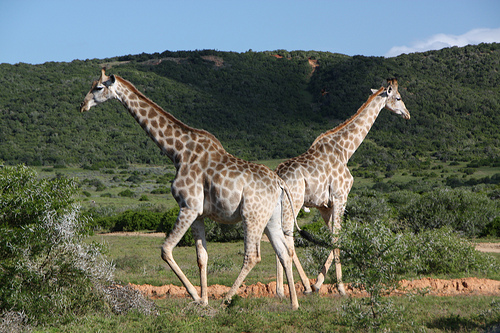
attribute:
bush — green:
[12, 159, 112, 328]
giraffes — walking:
[78, 64, 410, 311]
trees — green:
[431, 63, 476, 140]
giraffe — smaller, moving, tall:
[275, 78, 410, 299]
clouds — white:
[382, 22, 499, 57]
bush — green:
[334, 215, 474, 290]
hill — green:
[8, 45, 500, 208]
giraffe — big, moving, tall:
[75, 62, 302, 317]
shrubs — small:
[1, 164, 157, 331]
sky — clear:
[0, 1, 500, 64]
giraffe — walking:
[75, 67, 332, 313]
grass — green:
[0, 159, 497, 331]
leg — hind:
[217, 188, 274, 308]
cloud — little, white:
[392, 27, 489, 48]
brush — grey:
[41, 196, 160, 324]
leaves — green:
[436, 193, 461, 214]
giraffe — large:
[267, 73, 415, 298]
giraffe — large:
[72, 62, 354, 315]